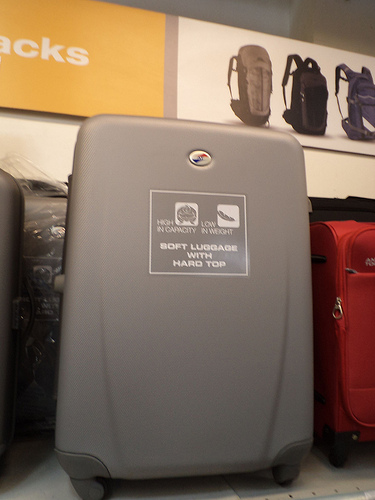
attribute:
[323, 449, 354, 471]
wheels — black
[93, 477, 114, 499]
wheels — black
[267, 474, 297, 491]
wheels — black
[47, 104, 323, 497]
luggage — grey, gray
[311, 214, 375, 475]
luggage — red, cloth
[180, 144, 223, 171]
logo — red, blue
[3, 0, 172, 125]
sign — yellow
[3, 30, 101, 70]
letters — white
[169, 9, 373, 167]
sign — oxymoron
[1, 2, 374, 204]
wall — white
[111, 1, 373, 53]
ceiling — white